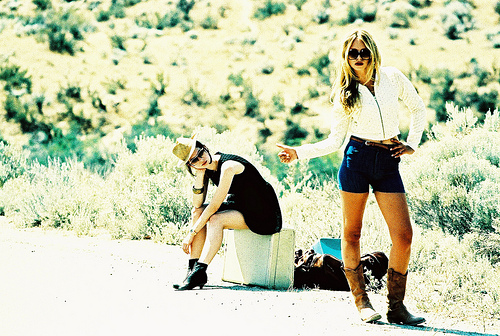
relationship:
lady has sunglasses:
[269, 23, 435, 329] [347, 48, 370, 58]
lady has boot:
[269, 23, 435, 329] [383, 265, 429, 329]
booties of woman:
[164, 254, 206, 289] [147, 119, 265, 293]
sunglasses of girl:
[187, 148, 207, 163] [158, 129, 285, 294]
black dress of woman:
[200, 146, 285, 236] [129, 97, 311, 322]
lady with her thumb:
[269, 23, 435, 329] [273, 141, 286, 148]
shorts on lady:
[335, 138, 402, 191] [269, 23, 435, 329]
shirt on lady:
[289, 66, 432, 158] [269, 23, 435, 329]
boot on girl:
[183, 260, 200, 272] [278, 26, 450, 333]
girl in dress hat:
[158, 129, 285, 294] [147, 126, 276, 295]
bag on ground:
[298, 244, 350, 290] [102, 194, 452, 306]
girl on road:
[158, 129, 285, 294] [9, 197, 348, 333]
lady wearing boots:
[269, 23, 435, 329] [164, 246, 232, 301]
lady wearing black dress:
[269, 23, 435, 329] [200, 149, 283, 236]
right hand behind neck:
[182, 154, 212, 201] [202, 148, 224, 169]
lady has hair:
[269, 23, 435, 329] [344, 34, 396, 87]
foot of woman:
[321, 240, 385, 333] [310, 37, 441, 327]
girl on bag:
[158, 129, 285, 294] [207, 195, 351, 325]